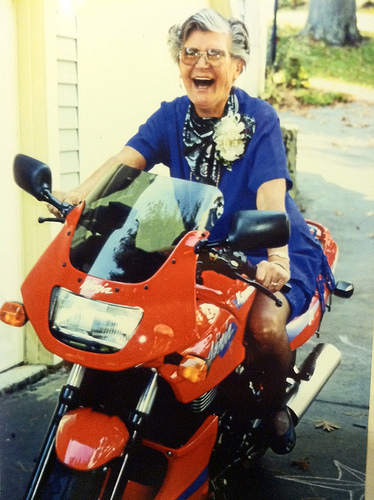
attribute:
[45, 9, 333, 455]
woman — older, sitting, smiling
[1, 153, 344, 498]
motorcycle — red, orange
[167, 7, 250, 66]
hair — gray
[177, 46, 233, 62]
glasses — tinted, eyes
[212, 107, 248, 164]
corsage — white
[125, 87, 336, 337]
dress — blue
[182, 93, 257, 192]
scarf — black, white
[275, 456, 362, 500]
chalk — drawing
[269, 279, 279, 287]
ring — wedding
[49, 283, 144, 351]
light — orange, white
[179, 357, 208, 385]
signal — left-turn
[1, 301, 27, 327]
signal — right-turn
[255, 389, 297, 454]
shoe — black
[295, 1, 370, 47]
trunk — brown, back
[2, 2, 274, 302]
house — yellow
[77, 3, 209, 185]
door — white